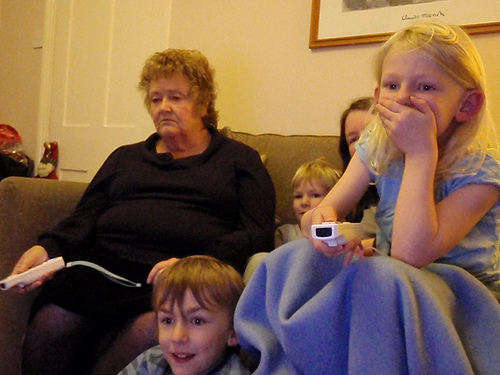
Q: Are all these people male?
A: No, they are both male and female.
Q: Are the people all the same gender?
A: No, they are both male and female.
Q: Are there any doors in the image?
A: Yes, there is a door.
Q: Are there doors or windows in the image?
A: Yes, there is a door.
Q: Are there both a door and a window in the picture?
A: No, there is a door but no windows.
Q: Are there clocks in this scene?
A: No, there are no clocks.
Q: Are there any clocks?
A: No, there are no clocks.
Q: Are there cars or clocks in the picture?
A: No, there are no clocks or cars.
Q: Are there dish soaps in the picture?
A: No, there are no dish soaps.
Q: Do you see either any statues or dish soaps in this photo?
A: No, there are no dish soaps or statues.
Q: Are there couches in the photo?
A: Yes, there is a couch.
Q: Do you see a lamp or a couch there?
A: Yes, there is a couch.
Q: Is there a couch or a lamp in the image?
A: Yes, there is a couch.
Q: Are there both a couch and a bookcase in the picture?
A: No, there is a couch but no bookcases.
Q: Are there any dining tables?
A: No, there are no dining tables.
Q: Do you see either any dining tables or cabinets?
A: No, there are no dining tables or cabinets.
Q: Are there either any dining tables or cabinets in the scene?
A: No, there are no dining tables or cabinets.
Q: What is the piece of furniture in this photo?
A: The piece of furniture is a couch.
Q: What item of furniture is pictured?
A: The piece of furniture is a couch.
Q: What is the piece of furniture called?
A: The piece of furniture is a couch.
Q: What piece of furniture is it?
A: The piece of furniture is a couch.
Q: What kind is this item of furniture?
A: This is a couch.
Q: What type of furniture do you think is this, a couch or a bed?
A: This is a couch.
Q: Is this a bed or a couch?
A: This is a couch.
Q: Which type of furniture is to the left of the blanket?
A: The piece of furniture is a couch.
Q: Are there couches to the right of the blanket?
A: No, the couch is to the left of the blanket.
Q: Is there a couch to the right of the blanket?
A: No, the couch is to the left of the blanket.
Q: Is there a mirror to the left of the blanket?
A: No, there is a couch to the left of the blanket.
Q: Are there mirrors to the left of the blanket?
A: No, there is a couch to the left of the blanket.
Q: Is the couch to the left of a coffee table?
A: No, the couch is to the left of the blanket.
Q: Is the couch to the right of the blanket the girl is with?
A: No, the couch is to the left of the blanket.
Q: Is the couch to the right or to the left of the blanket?
A: The couch is to the left of the blanket.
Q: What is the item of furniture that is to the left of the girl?
A: The piece of furniture is a couch.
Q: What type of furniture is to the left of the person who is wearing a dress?
A: The piece of furniture is a couch.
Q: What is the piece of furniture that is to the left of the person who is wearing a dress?
A: The piece of furniture is a couch.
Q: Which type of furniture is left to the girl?
A: The piece of furniture is a couch.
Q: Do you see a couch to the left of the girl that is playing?
A: Yes, there is a couch to the left of the girl.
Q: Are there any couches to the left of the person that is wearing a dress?
A: Yes, there is a couch to the left of the girl.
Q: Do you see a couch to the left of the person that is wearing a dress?
A: Yes, there is a couch to the left of the girl.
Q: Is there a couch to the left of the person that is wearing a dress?
A: Yes, there is a couch to the left of the girl.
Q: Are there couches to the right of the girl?
A: No, the couch is to the left of the girl.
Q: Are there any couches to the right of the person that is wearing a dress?
A: No, the couch is to the left of the girl.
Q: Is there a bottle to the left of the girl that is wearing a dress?
A: No, there is a couch to the left of the girl.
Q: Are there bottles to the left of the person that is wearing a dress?
A: No, there is a couch to the left of the girl.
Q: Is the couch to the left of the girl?
A: Yes, the couch is to the left of the girl.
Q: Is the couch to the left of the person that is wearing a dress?
A: Yes, the couch is to the left of the girl.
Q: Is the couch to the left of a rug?
A: No, the couch is to the left of the girl.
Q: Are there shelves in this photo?
A: No, there are no shelves.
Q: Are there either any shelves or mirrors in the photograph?
A: No, there are no shelves or mirrors.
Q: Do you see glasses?
A: No, there are no glasses.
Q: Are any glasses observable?
A: No, there are no glasses.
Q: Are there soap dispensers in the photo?
A: No, there are no soap dispensers.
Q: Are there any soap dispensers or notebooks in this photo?
A: No, there are no soap dispensers or notebooks.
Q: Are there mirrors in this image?
A: No, there are no mirrors.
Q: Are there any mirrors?
A: No, there are no mirrors.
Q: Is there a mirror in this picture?
A: No, there are no mirrors.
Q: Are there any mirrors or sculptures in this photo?
A: No, there are no mirrors or sculptures.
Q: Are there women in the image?
A: Yes, there is a woman.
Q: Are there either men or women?
A: Yes, there is a woman.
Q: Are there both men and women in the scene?
A: No, there is a woman but no men.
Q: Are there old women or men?
A: Yes, there is an old woman.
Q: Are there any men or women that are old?
A: Yes, the woman is old.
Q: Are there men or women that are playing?
A: Yes, the woman is playing.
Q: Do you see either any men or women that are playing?
A: Yes, the woman is playing.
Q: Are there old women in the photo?
A: Yes, there is an old woman.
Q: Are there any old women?
A: Yes, there is an old woman.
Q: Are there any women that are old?
A: Yes, there is a woman that is old.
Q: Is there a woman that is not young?
A: Yes, there is a old woman.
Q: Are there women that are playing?
A: Yes, there is a woman that is playing.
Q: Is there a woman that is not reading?
A: Yes, there is a woman that is playing.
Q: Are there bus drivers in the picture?
A: No, there are no bus drivers.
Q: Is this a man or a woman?
A: This is a woman.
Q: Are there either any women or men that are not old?
A: No, there is a woman but she is old.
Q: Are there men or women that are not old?
A: No, there is a woman but she is old.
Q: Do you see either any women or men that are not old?
A: No, there is a woman but she is old.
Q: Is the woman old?
A: Yes, the woman is old.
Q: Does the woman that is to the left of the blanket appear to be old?
A: Yes, the woman is old.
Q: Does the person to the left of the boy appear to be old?
A: Yes, the woman is old.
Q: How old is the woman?
A: The woman is old.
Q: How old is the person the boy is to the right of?
A: The woman is old.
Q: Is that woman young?
A: No, the woman is old.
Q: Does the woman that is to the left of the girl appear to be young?
A: No, the woman is old.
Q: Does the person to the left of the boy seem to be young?
A: No, the woman is old.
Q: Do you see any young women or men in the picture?
A: No, there is a woman but she is old.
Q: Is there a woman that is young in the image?
A: No, there is a woman but she is old.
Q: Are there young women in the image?
A: No, there is a woman but she is old.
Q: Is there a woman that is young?
A: No, there is a woman but she is old.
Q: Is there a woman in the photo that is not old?
A: No, there is a woman but she is old.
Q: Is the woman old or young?
A: The woman is old.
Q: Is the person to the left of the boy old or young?
A: The woman is old.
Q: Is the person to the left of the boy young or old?
A: The woman is old.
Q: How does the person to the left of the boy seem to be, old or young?
A: The woman is old.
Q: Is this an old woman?
A: Yes, this is an old woman.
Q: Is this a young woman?
A: No, this is an old woman.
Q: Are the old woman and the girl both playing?
A: Yes, both the woman and the girl are playing.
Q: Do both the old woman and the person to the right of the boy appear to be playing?
A: Yes, both the woman and the girl are playing.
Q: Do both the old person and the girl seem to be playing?
A: Yes, both the woman and the girl are playing.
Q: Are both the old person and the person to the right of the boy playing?
A: Yes, both the woman and the girl are playing.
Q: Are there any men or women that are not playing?
A: No, there is a woman but she is playing.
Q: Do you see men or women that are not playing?
A: No, there is a woman but she is playing.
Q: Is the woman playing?
A: Yes, the woman is playing.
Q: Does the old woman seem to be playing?
A: Yes, the woman is playing.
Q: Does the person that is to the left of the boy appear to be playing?
A: Yes, the woman is playing.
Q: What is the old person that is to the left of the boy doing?
A: The woman is playing.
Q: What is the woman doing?
A: The woman is playing.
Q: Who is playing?
A: The woman is playing.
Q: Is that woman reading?
A: No, the woman is playing.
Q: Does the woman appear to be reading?
A: No, the woman is playing.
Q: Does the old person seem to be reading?
A: No, the woman is playing.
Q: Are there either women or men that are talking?
A: No, there is a woman but she is playing.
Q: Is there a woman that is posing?
A: No, there is a woman but she is playing.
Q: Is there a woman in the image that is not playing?
A: No, there is a woman but she is playing.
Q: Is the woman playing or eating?
A: The woman is playing.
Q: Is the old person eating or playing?
A: The woman is playing.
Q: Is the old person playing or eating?
A: The woman is playing.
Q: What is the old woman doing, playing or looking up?
A: The woman is playing.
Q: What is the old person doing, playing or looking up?
A: The woman is playing.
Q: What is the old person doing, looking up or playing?
A: The woman is playing.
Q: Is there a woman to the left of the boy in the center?
A: Yes, there is a woman to the left of the boy.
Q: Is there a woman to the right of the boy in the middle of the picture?
A: No, the woman is to the left of the boy.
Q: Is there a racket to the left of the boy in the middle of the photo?
A: No, there is a woman to the left of the boy.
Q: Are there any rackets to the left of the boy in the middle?
A: No, there is a woman to the left of the boy.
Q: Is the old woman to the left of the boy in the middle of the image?
A: Yes, the woman is to the left of the boy.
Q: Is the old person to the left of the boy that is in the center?
A: Yes, the woman is to the left of the boy.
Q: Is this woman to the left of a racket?
A: No, the woman is to the left of the boy.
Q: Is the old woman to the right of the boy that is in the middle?
A: No, the woman is to the left of the boy.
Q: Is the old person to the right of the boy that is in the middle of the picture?
A: No, the woman is to the left of the boy.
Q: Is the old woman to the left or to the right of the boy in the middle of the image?
A: The woman is to the left of the boy.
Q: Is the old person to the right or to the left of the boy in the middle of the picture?
A: The woman is to the left of the boy.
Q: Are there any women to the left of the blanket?
A: Yes, there is a woman to the left of the blanket.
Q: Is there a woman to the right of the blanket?
A: No, the woman is to the left of the blanket.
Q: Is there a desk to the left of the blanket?
A: No, there is a woman to the left of the blanket.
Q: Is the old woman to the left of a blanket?
A: Yes, the woman is to the left of a blanket.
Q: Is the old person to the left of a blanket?
A: Yes, the woman is to the left of a blanket.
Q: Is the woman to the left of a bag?
A: No, the woman is to the left of a blanket.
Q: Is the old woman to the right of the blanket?
A: No, the woman is to the left of the blanket.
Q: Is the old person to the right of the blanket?
A: No, the woman is to the left of the blanket.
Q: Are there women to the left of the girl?
A: Yes, there is a woman to the left of the girl.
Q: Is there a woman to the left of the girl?
A: Yes, there is a woman to the left of the girl.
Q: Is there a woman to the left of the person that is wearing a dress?
A: Yes, there is a woman to the left of the girl.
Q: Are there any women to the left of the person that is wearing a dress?
A: Yes, there is a woman to the left of the girl.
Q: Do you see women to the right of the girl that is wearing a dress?
A: No, the woman is to the left of the girl.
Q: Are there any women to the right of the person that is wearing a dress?
A: No, the woman is to the left of the girl.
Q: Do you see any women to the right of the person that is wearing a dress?
A: No, the woman is to the left of the girl.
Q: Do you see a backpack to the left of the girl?
A: No, there is a woman to the left of the girl.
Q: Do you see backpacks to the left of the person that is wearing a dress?
A: No, there is a woman to the left of the girl.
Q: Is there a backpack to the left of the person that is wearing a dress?
A: No, there is a woman to the left of the girl.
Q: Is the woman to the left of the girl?
A: Yes, the woman is to the left of the girl.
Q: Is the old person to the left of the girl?
A: Yes, the woman is to the left of the girl.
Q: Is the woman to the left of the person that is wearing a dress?
A: Yes, the woman is to the left of the girl.